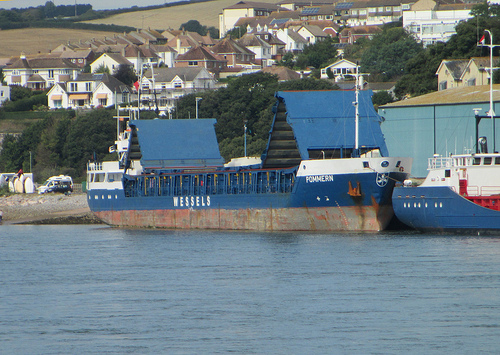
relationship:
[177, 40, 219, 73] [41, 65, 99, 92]
house has overhangs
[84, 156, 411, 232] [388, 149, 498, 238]
boat pull boat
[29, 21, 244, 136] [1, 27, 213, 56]
houses has roofs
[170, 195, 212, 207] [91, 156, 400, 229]
wessels on boat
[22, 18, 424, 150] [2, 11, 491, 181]
trees on land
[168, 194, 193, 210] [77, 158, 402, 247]
w on boat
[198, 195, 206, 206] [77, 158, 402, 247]
letter l on boat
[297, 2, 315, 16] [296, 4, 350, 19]
solar panel on roof